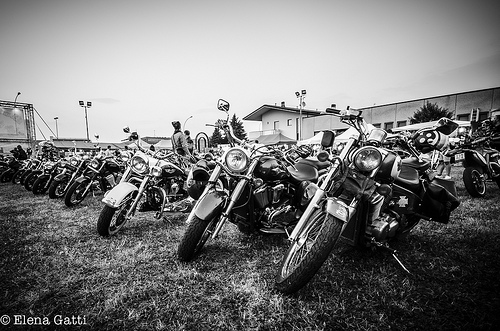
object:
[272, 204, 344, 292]
wheel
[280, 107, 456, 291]
motorcycle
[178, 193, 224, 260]
wheel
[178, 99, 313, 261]
motorcycle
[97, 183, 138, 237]
wheel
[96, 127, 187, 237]
motorcycle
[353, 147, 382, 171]
light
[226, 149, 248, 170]
light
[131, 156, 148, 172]
light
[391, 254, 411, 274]
kickstand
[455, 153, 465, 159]
plate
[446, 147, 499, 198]
motorcycle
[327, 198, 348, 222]
fender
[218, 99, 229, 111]
mirror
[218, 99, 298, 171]
handlebar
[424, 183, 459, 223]
bags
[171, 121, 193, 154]
people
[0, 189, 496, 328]
grass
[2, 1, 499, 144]
sky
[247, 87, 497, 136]
building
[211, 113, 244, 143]
tree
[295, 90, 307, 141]
post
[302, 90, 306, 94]
lights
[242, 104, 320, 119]
roof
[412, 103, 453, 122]
tree